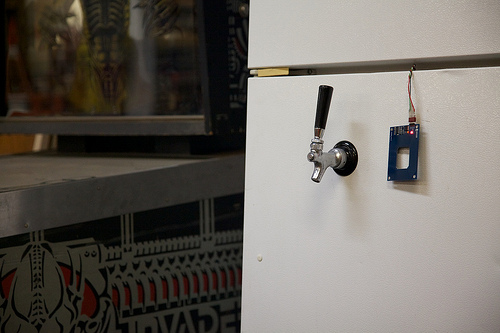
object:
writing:
[122, 295, 242, 332]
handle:
[313, 83, 334, 131]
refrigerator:
[240, 2, 497, 330]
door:
[241, 65, 498, 326]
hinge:
[250, 65, 311, 78]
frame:
[1, 1, 230, 135]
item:
[378, 123, 418, 182]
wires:
[408, 66, 415, 121]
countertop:
[0, 149, 243, 242]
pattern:
[0, 188, 245, 329]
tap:
[305, 84, 356, 184]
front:
[238, 1, 498, 327]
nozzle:
[311, 167, 321, 184]